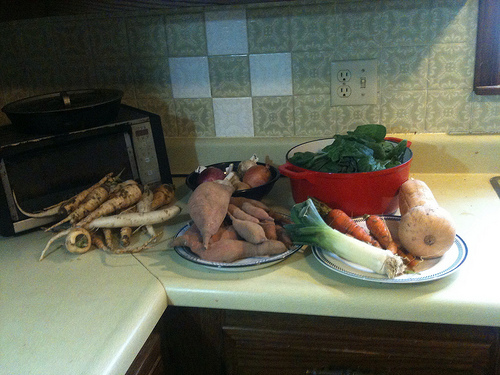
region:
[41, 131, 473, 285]
vegetables on the counter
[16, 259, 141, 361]
white counter top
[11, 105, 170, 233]
a microwave on the counter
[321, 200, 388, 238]
carrots on a plate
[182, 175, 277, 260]
potatoes on a plate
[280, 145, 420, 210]
a red pot on the counter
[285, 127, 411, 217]
a red pot with lettuce leaves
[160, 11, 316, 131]
tiles on the wall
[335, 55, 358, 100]
an electrical socket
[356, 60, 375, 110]
a light switch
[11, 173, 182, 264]
The parsnips are on the table.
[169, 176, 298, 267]
The sweet potatoes are on a plate.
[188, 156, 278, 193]
The onions are in a bowl.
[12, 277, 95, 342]
The counter is white.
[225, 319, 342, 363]
The cabinets are brown.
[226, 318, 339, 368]
The cabinets are made from wood.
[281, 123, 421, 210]
The greens are in a pot.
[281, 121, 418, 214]
The pot is red.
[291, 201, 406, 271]
The leek is on the plate.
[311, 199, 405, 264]
The carrots are on a plate.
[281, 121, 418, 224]
red bowl with steamed spinage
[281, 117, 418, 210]
red bowl with dark green leaf vegetables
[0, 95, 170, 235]
black microwave on the counter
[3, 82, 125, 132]
a flat sauce pan on the microwave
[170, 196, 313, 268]
sweet potatoes on a plate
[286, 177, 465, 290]
vegetables on top of a white plate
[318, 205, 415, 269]
fresh raw carrots on a plate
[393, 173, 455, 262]
a squash on top of a plate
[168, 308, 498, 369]
dark brown cabinets under the counter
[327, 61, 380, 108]
an outlet and switch on the wall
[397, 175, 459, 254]
yellow squash on the plate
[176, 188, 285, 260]
sweet potato in different sizes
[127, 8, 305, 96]
brown and white tiles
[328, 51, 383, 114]
switch and electric plug in the wall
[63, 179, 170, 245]
white radishes near the micrwave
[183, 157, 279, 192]
Onions in the black bowl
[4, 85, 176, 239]
microwave in the counter top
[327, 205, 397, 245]
two carrots in the plate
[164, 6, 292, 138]
Four white tiles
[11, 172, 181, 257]
The parsnips are on the table.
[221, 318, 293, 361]
The cabinets are brown.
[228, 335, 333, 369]
The cabinets are made from wood.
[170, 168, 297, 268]
The sweet potatoes are on a plate.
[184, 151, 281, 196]
The onions are in a bowl.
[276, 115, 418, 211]
The greens are in a pot.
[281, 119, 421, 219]
The pot is red.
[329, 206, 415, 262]
The carrots are on a plate.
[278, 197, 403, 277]
The leek is on a plate.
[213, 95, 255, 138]
white tile on wall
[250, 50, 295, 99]
white tile on wall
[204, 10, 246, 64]
white tile on wall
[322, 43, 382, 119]
A light switch with outlet built-in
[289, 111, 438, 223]
A red bowl with green lettuce in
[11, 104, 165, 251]
An older microwave that is rusted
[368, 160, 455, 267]
Acorn squash on a plate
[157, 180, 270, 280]
Sweet potatoes on a plate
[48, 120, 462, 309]
Garden vegetables on the countertop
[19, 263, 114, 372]
White countertop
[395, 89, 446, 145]
Green white tile on the wall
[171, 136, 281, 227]
Onions and applicable